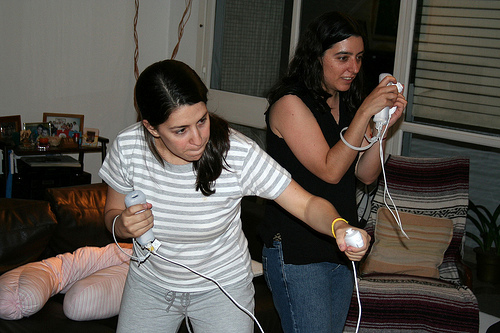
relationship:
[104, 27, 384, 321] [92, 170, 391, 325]
woman holding remote controls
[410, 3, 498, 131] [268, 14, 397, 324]
blind beside girl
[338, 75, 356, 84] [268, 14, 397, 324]
mouth of girl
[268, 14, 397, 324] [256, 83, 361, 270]
girl wearing shirt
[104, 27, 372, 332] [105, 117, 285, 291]
woman wearing shirt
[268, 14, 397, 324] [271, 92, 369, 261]
girl wearing shirt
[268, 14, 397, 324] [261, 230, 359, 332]
girl wearing jeans